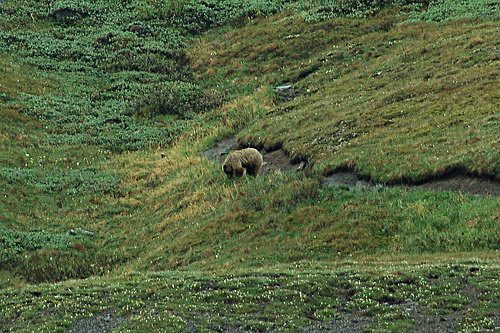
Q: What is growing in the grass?
A: Small flowers.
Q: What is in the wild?
A: Brown bear.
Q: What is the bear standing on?
A: The ground.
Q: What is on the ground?
A: Weeds and grass.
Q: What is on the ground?
A: Wild grass.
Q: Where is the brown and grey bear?
A: In the grass.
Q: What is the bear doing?
A: Eating.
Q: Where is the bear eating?
A: In the wilderness.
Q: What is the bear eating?
A: Yellow and green grass.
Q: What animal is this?
A: Bear.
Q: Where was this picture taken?
A: A field.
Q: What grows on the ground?
A: Grass.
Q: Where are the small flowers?
A: In the grass.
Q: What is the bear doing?
A: Eating.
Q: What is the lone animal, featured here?
A: A bear.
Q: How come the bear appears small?
A: The picture was taken from a distance, without a zoom lens.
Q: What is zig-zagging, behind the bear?
A: An uneven, dirt path.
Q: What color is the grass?
A: Green.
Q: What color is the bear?
A: Brown.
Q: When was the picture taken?
A: Daytime.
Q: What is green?
A: The grass.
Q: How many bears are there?
A: One.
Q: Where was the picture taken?
A: In a meadow.